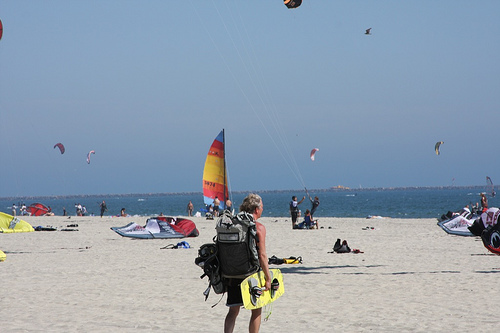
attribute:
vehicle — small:
[109, 213, 197, 246]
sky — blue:
[9, 4, 477, 208]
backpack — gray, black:
[212, 213, 259, 280]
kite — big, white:
[306, 148, 320, 161]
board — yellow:
[237, 260, 297, 310]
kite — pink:
[295, 126, 345, 159]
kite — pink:
[423, 126, 458, 165]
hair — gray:
[235, 183, 267, 217]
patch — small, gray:
[218, 232, 240, 244]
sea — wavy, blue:
[0, 184, 497, 217]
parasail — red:
[53, 142, 65, 154]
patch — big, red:
[23, 194, 50, 224]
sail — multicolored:
[202, 130, 229, 210]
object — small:
[162, 239, 191, 249]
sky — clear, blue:
[2, 2, 499, 198]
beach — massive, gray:
[4, 214, 499, 332]